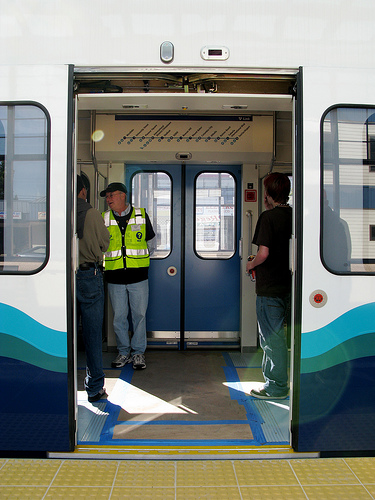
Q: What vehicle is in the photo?
A: A train.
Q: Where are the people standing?
A: On the train.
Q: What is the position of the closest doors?
A: Opened.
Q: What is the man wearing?
A: Black shirt and jeans.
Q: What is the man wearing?
A: Grey shirt and jeans.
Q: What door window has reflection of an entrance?
A: Left one.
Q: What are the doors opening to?
A: Inside of train.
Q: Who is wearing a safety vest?
A: A man.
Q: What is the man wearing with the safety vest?
A: Jeans and shirt.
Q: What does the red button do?
A: Open doors.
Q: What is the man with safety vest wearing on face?
A: Glasses.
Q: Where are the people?
A: On a train.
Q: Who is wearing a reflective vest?
A: The man standing in front of the door.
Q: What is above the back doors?
A: A map of the stops.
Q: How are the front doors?
A: Open.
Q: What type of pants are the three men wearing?
A: Jeans.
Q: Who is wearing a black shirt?
A: The man on the right.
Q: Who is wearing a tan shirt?
A: The man on the left.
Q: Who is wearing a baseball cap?
A: The man in the reflective vest.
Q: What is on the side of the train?
A: Stripes.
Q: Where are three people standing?
A: In a train.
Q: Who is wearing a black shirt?
A: Man on the right.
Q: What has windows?
A: The train.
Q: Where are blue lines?
A: On train's floor.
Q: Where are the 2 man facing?
A: Towards the back door.